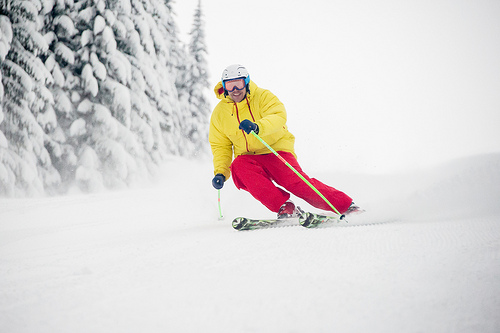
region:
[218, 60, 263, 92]
white helmet on man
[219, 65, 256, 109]
man in white helmet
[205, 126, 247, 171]
right arm on man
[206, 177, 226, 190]
right hand on man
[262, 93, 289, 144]
left arm on man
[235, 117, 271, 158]
left hand on man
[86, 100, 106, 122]
white snow on tree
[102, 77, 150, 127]
white snow on tree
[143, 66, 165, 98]
white snow on tree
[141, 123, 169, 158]
white snow on tree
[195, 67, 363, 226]
skier coming down the mountain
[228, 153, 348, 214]
red pants worn by the skier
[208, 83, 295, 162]
yellow hooded sweatshirt skier is wearing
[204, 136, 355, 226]
neon ski poles skier is holding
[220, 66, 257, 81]
white helmet skier is wearing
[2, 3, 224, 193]
trees covered in snow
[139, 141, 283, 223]
snow dust kicked up by skier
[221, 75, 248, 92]
ski goggles worn by skier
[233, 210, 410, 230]
white skis with black and green accents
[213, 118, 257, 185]
navy blue gloves skier is wearing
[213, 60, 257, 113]
head of a person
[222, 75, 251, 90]
goggle of a person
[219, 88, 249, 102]
mouth of a person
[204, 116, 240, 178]
arm of a person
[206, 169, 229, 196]
hand of a person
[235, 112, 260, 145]
hand of a person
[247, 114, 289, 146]
arm of a person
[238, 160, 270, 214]
leg of a person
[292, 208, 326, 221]
feet of a person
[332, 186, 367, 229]
feet of a person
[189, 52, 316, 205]
man skiing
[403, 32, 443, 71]
white clouds in blue sky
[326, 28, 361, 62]
white clouds in blue sky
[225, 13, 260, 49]
white clouds in blue sky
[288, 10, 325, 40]
white clouds in blue sky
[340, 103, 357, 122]
white clouds in blue sky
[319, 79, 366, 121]
white clouds in blue sky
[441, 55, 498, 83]
white clouds in blue sky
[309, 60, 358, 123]
white clouds in blue sky